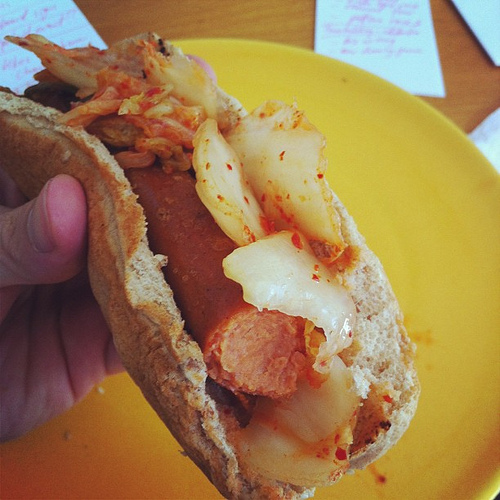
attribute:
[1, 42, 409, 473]
hot dog — pink, bitten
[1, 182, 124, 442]
hand — white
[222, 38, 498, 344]
dish — yellow, round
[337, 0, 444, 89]
paper — white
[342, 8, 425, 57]
writing — red, pink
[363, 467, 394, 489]
spot — red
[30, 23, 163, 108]
cheese — gooey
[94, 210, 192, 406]
bread — brown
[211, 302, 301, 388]
sausage — pink, polish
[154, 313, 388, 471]
bun — toasted, brown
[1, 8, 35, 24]
writing — red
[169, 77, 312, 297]
onion — white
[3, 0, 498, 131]
table — brown